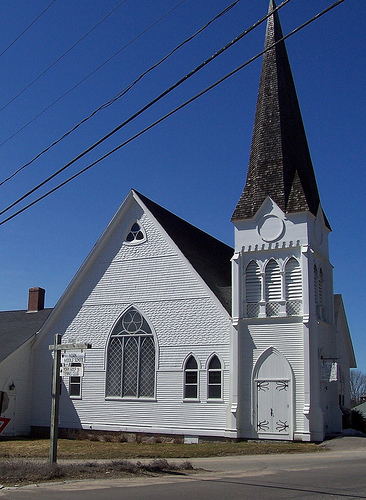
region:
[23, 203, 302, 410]
This is a church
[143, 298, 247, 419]
The church is white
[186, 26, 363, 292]
The steeple is tall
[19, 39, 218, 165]
The sky is blue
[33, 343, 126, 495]
There is a sign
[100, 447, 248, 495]
The grass is brown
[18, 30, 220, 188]
There are power lines above the church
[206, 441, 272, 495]
The road is gray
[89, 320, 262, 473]
The church has very nice windows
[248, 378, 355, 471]
The door is shut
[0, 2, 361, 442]
a Victorian looking church building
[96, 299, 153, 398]
a church's arched shaped windwo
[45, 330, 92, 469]
a street sign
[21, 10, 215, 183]
telephone wire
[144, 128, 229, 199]
a bright blue sky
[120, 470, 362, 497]
the street in front of a church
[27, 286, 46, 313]
the chimney of a church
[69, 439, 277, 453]
grass in front of a church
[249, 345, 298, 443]
the entrance to a church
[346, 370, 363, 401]
a tree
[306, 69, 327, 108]
part of the sky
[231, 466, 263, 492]
part of a shade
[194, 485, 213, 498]
part of a road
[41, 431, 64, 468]
part of a post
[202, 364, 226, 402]
part of a window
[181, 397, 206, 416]
part of a wall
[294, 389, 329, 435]
edge of a house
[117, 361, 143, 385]
part of a window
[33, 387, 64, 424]
part of a post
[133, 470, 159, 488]
edge of a road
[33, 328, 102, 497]
There is a sign outside the church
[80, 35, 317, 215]
The sky is blue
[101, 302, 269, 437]
The windows are nicely shaped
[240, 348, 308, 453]
The door is shut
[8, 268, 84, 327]
There is a brick chimney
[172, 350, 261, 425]
There are two windows here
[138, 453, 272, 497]
The road is near the church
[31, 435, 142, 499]
The ground is brown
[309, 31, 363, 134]
this is the sky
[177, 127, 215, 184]
the sky is blue in color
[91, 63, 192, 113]
these are electrical wires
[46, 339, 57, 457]
this is a pole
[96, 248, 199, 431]
this is a building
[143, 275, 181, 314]
the building is white in color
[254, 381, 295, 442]
this is the door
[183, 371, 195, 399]
this is the window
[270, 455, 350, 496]
this is a pavement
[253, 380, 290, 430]
the door is closed